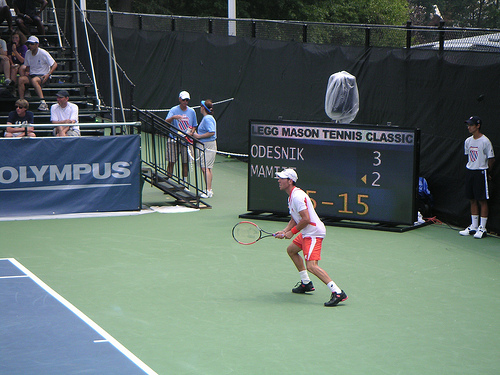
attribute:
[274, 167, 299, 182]
hat — white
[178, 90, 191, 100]
hat — white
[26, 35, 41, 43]
hat — white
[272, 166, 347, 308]
man — playing tennis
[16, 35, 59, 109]
man — watching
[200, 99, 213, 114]
visor — blue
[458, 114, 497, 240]
man — standing, watching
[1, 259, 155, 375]
tennis court — blue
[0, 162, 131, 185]
olympus — white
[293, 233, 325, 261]
shorts — red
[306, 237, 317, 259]
stripe — white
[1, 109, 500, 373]
court — at tennis playfield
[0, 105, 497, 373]
floor — rough green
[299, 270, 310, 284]
sock — white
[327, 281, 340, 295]
sock — white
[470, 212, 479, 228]
sock — white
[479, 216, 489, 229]
sock — white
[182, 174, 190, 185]
sock — white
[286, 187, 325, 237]
shirt — white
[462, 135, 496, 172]
shirt — white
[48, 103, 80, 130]
shirt — white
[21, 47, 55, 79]
shirt — white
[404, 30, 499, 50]
tent — black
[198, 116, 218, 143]
blouse — light blue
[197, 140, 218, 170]
shorts — white, khaki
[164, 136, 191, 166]
shorts — white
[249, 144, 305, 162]
word — white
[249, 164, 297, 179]
word — white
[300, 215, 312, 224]
elbow — bent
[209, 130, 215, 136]
elbow — bent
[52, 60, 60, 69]
elbow — bent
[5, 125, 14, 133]
elbow — bent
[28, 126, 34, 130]
elbow — bent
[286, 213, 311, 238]
skin — light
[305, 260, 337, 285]
skin — light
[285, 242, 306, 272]
skin — light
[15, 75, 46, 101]
skin — light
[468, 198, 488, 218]
skin — light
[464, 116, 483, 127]
cap — black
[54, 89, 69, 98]
cap — black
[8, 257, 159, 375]
line — white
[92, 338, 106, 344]
line — white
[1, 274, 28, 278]
line — white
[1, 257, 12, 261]
line — white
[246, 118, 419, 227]
score board — digital, black, white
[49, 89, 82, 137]
man — watching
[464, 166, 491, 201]
shorts — black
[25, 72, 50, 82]
shorts — black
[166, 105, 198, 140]
shirt — light blue